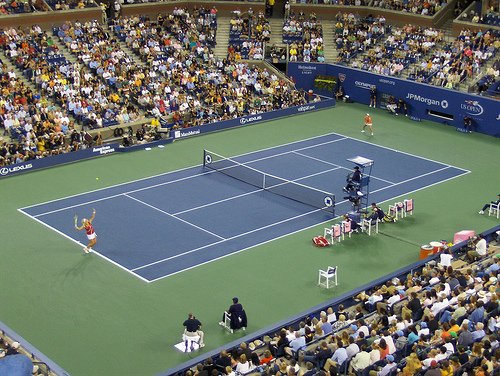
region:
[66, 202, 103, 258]
a tennis player getting ready to hit the ball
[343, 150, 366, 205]
the referee of the game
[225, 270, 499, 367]
part of the audience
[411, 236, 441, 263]
coolers full of drinks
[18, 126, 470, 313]
the blue tennis court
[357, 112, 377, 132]
the other tennis player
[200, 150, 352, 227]
the net for the game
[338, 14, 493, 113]
more of the audience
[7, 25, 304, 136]
and even more audience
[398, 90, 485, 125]
sponsors for the game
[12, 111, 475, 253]
two people playing tennis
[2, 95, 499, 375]
a green and blue tennis court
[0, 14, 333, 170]
bleachers filled with people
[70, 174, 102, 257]
a tennis player about to hit a tennis ball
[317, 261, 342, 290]
an empty white chair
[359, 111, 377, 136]
a tennis player wearing red and white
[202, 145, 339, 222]
a tennis court net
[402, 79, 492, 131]
advertisements on a wall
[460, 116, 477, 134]
a person crouched down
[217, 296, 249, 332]
a person sitting in a chair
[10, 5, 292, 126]
spectators at a tennis match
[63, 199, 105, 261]
player serving a tennis ball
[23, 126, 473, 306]
blue tennis court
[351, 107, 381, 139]
opposing tennis player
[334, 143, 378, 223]
judge of tennis game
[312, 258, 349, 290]
white chair on tennis court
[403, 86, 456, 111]
jp morgan advertising on wall around tennis court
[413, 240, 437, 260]
orange and white drink cooler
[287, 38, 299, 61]
spectator in a yellow shirt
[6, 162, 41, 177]
lexus advertisement on blue wall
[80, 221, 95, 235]
the shirt is red colored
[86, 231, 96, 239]
the player is wearing white shorts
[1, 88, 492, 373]
the tennis court is blue and green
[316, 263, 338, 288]
the chair is white in color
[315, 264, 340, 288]
the chair is empty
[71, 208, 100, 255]
the player has arms up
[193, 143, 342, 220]
the tennis net is black and white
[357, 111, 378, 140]
the player is wearing a red and white outfit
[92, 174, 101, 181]
the ball is up in the air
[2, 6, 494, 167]
the spectators are watching the game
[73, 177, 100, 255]
the girl is hitting ball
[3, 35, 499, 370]
crowd is big and full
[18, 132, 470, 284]
court is long and blue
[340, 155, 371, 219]
man is sitting on big chair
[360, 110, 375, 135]
girl is waiting for ball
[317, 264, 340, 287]
chair is white and empty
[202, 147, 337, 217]
net is on poles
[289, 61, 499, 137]
signs have ads and it's blue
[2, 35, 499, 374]
people are watching players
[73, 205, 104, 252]
girl is wearing white skirt